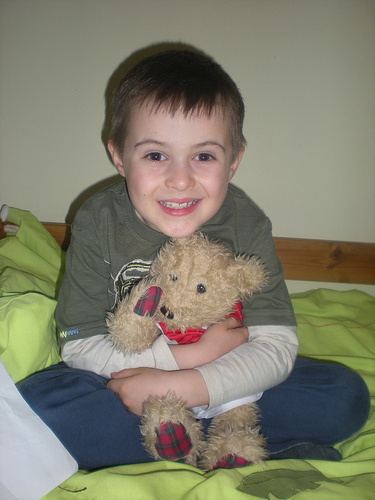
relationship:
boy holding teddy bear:
[13, 51, 370, 469] [108, 235, 268, 472]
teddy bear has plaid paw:
[108, 235, 268, 472] [134, 287, 162, 317]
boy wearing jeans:
[13, 51, 370, 469] [13, 362, 370, 471]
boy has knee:
[13, 51, 370, 469] [319, 359, 369, 445]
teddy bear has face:
[108, 235, 268, 472] [147, 234, 230, 325]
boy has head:
[13, 51, 370, 469] [106, 49, 245, 243]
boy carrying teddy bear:
[13, 51, 370, 469] [108, 235, 268, 472]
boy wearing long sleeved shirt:
[13, 51, 370, 469] [61, 323, 300, 412]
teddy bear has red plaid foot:
[108, 235, 268, 472] [151, 422, 194, 461]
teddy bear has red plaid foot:
[108, 235, 268, 472] [213, 453, 253, 471]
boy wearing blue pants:
[13, 51, 370, 469] [13, 362, 370, 471]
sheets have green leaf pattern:
[3, 204, 372, 498] [240, 470, 327, 500]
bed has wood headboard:
[1, 203, 372, 497] [39, 221, 372, 287]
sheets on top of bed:
[3, 204, 372, 498] [1, 203, 372, 497]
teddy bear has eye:
[108, 235, 268, 472] [195, 283, 205, 293]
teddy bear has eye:
[108, 235, 268, 472] [170, 276, 178, 283]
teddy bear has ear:
[108, 235, 268, 472] [224, 255, 267, 296]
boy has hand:
[13, 51, 370, 469] [108, 365, 210, 414]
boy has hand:
[13, 51, 370, 469] [165, 318, 248, 367]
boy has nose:
[13, 51, 370, 469] [165, 164, 197, 189]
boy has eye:
[13, 51, 370, 469] [141, 150, 168, 162]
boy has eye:
[13, 51, 370, 469] [190, 150, 215, 162]